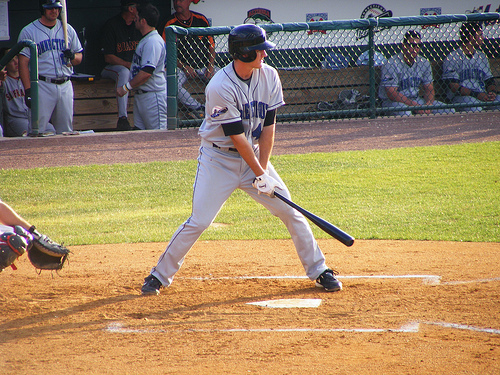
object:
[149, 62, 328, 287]
gray uniform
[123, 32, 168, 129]
gray uniform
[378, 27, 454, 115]
gray uniform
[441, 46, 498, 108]
gray uniform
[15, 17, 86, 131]
gray uniform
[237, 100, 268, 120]
blue letters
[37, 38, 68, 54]
blue letters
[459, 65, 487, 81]
blue letters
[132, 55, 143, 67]
blue letters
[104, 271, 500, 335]
box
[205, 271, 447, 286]
line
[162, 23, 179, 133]
post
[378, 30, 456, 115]
baseball player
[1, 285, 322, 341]
shadows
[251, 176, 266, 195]
hand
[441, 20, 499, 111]
baseball player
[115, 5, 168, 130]
baseball player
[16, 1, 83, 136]
baseball player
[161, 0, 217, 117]
baseball player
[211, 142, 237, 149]
belt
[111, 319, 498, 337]
lines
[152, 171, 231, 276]
legs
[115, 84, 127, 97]
hands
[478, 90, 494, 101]
hands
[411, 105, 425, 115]
hands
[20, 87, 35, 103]
hands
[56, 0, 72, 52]
bat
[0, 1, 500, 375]
tennis court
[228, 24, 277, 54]
baseball cap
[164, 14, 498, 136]
fence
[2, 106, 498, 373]
baseball field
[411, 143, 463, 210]
grass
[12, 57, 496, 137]
bench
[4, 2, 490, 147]
dugout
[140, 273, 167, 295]
sneakers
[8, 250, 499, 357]
dirt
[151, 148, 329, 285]
pants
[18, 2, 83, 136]
player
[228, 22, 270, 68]
head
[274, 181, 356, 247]
bat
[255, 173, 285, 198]
hand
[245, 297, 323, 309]
plate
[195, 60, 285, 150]
shirt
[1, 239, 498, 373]
sand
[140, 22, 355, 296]
baseball player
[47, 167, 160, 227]
grass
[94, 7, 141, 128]
man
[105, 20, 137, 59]
black shirt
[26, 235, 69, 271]
glove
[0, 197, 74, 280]
catcher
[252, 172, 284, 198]
glove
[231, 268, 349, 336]
home plate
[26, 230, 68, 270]
hand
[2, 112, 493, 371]
field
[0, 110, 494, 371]
ground